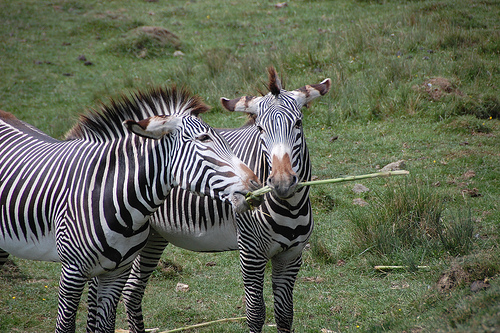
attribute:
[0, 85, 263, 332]
zebra — black, standing, feed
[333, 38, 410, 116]
grass — green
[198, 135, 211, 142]
eye — open, dark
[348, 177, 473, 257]
grass — tall